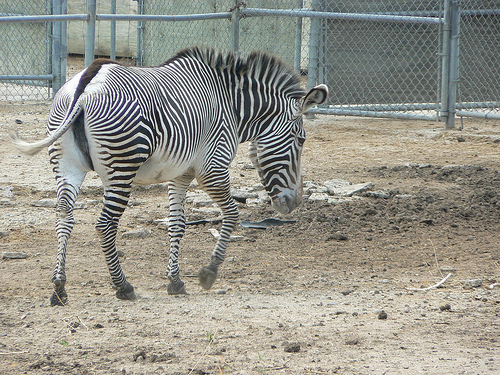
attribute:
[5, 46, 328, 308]
zebra — striped, walking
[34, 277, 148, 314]
hooves — rear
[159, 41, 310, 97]
mane — zebra's, short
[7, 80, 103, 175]
tail — short, zebra's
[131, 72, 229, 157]
stripes — black, white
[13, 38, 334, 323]
zebra — walking, striped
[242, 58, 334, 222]
head — white, black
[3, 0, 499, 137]
fence — cage, chain link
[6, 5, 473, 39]
pipe — large, grey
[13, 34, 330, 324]
animal — black, white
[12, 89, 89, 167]
tail — white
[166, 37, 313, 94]
mane — white, black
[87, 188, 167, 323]
leg — hind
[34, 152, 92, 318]
leg — hind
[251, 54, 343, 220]
head — down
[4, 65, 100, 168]
tail — zebra, swinging left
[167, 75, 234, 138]
stripes — black, white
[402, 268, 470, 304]
stick — white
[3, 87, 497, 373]
dirt — dry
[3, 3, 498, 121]
fence — metal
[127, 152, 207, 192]
belly — white